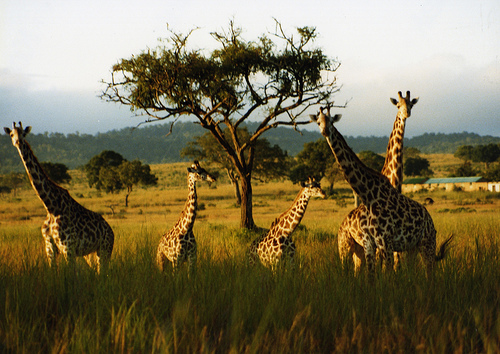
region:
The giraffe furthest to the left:
[5, 122, 118, 279]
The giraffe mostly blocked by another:
[337, 91, 424, 282]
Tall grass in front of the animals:
[0, 246, 497, 353]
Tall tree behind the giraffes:
[104, 15, 344, 224]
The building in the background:
[412, 173, 499, 200]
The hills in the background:
[0, 112, 492, 171]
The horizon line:
[2, 115, 495, 140]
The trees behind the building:
[13, 131, 498, 201]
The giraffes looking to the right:
[153, 161, 332, 278]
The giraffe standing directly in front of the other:
[306, 107, 442, 282]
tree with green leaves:
[110, 14, 325, 249]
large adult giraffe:
[3, 114, 118, 288]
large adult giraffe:
[310, 106, 382, 291]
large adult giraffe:
[367, 83, 456, 282]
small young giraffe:
[149, 153, 226, 290]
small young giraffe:
[248, 173, 330, 289]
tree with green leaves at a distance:
[80, 146, 182, 218]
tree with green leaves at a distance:
[453, 138, 498, 176]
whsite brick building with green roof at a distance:
[420, 166, 498, 206]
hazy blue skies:
[29, 26, 87, 131]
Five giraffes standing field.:
[8, 87, 456, 307]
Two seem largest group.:
[312, 86, 457, 285]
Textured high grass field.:
[6, 270, 493, 345]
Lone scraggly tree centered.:
[205, 12, 278, 200]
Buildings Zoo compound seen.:
[405, 169, 497, 204]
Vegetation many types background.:
[35, 121, 213, 161]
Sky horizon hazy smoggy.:
[2, 68, 141, 123]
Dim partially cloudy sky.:
[341, 8, 499, 83]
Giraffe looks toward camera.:
[7, 113, 124, 271]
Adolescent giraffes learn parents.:
[147, 159, 325, 275]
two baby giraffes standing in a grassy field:
[151, 157, 328, 284]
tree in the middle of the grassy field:
[101, 14, 350, 258]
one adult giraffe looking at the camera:
[0, 120, 117, 274]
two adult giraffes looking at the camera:
[310, 76, 438, 301]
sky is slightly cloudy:
[0, 0, 495, 135]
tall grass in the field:
[0, 237, 498, 351]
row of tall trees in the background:
[0, 120, 498, 171]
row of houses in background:
[397, 174, 498, 198]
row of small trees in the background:
[2, 147, 498, 200]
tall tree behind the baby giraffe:
[111, 17, 342, 248]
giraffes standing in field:
[6, 73, 448, 295]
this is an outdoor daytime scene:
[9, 0, 491, 344]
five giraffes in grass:
[8, 74, 446, 317]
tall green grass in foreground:
[6, 207, 499, 343]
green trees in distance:
[6, 124, 498, 201]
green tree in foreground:
[104, 18, 339, 239]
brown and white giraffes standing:
[4, 82, 447, 309]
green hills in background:
[2, 113, 499, 178]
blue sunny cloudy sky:
[1, 5, 499, 137]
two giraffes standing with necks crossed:
[307, 73, 454, 288]